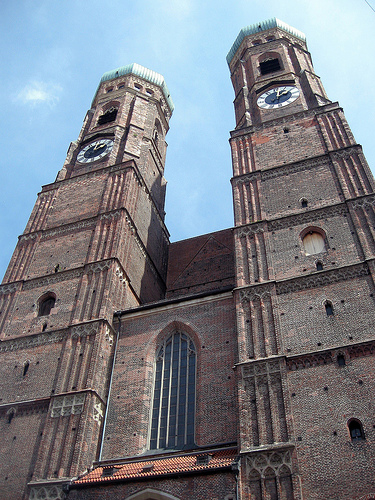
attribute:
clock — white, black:
[75, 138, 115, 163]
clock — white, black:
[256, 86, 299, 111]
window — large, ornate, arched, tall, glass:
[144, 328, 200, 450]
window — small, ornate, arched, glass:
[38, 296, 55, 315]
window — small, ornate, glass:
[348, 421, 364, 442]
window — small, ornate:
[336, 352, 346, 367]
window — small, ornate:
[324, 299, 335, 317]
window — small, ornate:
[316, 259, 324, 272]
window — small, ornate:
[300, 198, 309, 208]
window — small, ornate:
[283, 126, 290, 134]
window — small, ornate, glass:
[256, 59, 284, 75]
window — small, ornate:
[7, 408, 15, 425]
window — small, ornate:
[22, 361, 30, 379]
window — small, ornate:
[40, 322, 50, 333]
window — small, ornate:
[53, 263, 61, 272]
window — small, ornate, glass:
[96, 108, 118, 125]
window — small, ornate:
[153, 131, 161, 150]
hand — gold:
[94, 140, 100, 151]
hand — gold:
[96, 142, 108, 150]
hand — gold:
[276, 86, 281, 96]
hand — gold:
[278, 88, 291, 96]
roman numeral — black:
[257, 99, 265, 104]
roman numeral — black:
[261, 103, 267, 108]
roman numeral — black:
[267, 103, 274, 108]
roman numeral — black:
[77, 153, 85, 156]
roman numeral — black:
[79, 157, 85, 163]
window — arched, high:
[105, 86, 114, 92]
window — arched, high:
[119, 82, 127, 90]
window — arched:
[134, 83, 143, 93]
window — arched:
[266, 34, 276, 42]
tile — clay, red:
[72, 445, 241, 487]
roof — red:
[68, 445, 238, 486]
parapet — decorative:
[100, 62, 177, 117]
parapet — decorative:
[222, 19, 307, 62]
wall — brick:
[98, 296, 238, 466]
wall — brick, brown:
[233, 35, 375, 499]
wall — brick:
[163, 231, 235, 293]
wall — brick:
[68, 469, 237, 499]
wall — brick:
[1, 81, 172, 485]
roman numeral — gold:
[278, 102, 283, 110]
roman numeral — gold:
[286, 99, 293, 104]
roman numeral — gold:
[289, 94, 302, 99]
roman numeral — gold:
[89, 155, 97, 163]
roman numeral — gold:
[98, 153, 103, 156]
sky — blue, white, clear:
[1, 1, 374, 283]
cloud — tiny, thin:
[13, 77, 62, 117]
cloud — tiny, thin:
[176, 186, 205, 233]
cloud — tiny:
[120, 1, 195, 65]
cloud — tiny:
[30, 6, 73, 83]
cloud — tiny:
[293, 2, 364, 40]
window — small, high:
[145, 87, 153, 97]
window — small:
[160, 97, 165, 109]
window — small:
[163, 107, 171, 117]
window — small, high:
[252, 38, 264, 47]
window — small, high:
[283, 35, 291, 43]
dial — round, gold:
[76, 140, 111, 162]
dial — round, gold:
[256, 87, 300, 109]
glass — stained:
[150, 334, 197, 450]